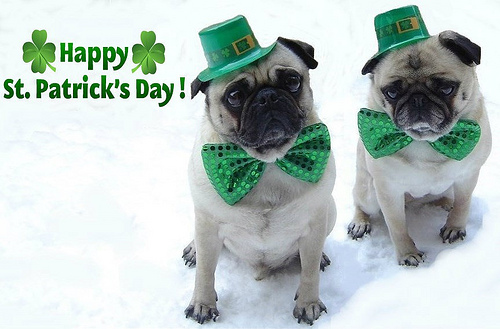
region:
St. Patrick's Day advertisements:
[3, 11, 495, 327]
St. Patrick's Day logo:
[1, 23, 190, 110]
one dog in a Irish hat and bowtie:
[176, 13, 330, 326]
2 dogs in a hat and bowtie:
[171, 10, 487, 326]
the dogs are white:
[168, 14, 498, 274]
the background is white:
[9, 20, 396, 327]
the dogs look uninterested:
[190, 6, 490, 166]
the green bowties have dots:
[190, 106, 485, 216]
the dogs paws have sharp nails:
[171, 216, 491, 322]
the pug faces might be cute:
[235, 85, 451, 196]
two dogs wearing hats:
[187, 16, 483, 267]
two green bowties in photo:
[215, 112, 480, 217]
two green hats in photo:
[196, 16, 428, 71]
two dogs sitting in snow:
[146, 80, 478, 322]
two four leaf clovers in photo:
[2, 20, 167, 76]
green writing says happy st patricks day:
[10, 70, 192, 105]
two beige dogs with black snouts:
[202, 66, 482, 152]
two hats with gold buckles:
[190, 12, 460, 62]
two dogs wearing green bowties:
[182, 50, 484, 217]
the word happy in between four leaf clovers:
[14, 24, 176, 76]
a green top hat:
[181, 9, 291, 94]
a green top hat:
[338, 6, 445, 83]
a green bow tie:
[180, 111, 342, 212]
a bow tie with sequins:
[349, 108, 480, 170]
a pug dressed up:
[353, 13, 486, 283]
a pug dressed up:
[176, 10, 334, 323]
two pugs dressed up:
[153, 3, 478, 312]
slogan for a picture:
[0, 32, 196, 112]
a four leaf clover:
[128, 20, 163, 85]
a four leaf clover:
[26, 35, 58, 74]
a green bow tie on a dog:
[199, 118, 331, 201]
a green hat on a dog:
[355, 8, 444, 72]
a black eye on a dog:
[219, 82, 252, 112]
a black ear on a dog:
[435, 27, 482, 67]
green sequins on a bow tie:
[216, 160, 239, 181]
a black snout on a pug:
[241, 85, 296, 140]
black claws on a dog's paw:
[288, 288, 333, 325]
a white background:
[1, 3, 496, 324]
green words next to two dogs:
[0, 26, 185, 107]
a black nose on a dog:
[257, 87, 277, 107]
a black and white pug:
[177, 14, 334, 326]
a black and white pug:
[328, 9, 488, 261]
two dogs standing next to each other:
[174, 23, 494, 324]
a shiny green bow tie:
[200, 122, 332, 209]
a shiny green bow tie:
[352, 100, 482, 166]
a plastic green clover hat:
[190, 12, 276, 87]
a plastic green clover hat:
[354, 2, 444, 78]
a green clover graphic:
[18, 25, 54, 75]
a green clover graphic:
[127, 27, 171, 76]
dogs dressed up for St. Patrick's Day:
[170, 0, 493, 327]